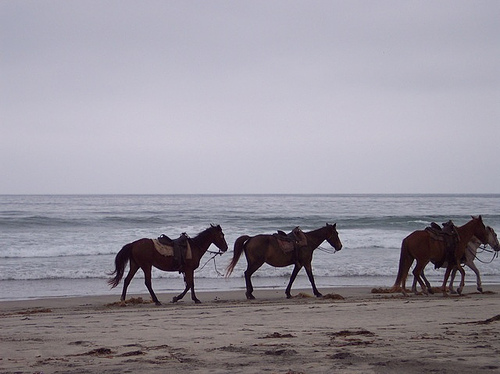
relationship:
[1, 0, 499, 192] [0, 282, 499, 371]
sky by beach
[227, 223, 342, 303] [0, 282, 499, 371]
horse on beach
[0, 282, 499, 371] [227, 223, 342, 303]
beach under horse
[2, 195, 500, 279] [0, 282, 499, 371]
ocean by beach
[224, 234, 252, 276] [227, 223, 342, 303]
tail on horse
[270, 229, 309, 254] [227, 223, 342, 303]
saddle on horse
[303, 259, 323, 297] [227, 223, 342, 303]
leg on horse